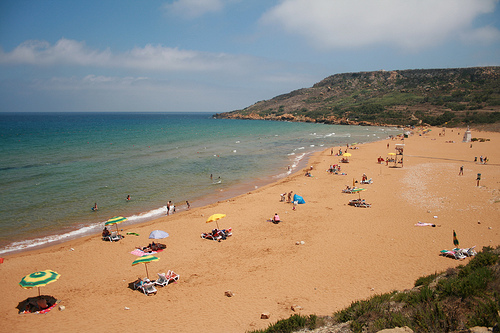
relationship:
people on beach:
[266, 130, 484, 245] [5, 129, 479, 331]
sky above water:
[1, 2, 493, 115] [1, 114, 366, 252]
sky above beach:
[1, 2, 493, 115] [5, 129, 479, 331]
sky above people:
[1, 2, 493, 115] [266, 130, 484, 245]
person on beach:
[167, 199, 174, 213] [1, 112, 496, 329]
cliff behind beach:
[216, 65, 499, 131] [1, 112, 496, 329]